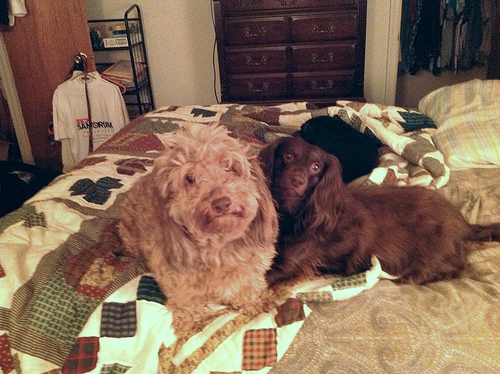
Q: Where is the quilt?
A: On the bed.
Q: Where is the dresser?
A: Against the back wall.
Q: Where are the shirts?
A: Hanging on the doorknob.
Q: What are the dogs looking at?
A: The camera.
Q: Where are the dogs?
A: On the bed.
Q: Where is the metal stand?
A: Behind the door.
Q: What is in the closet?
A: Clothing.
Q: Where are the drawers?
A: In the dresser.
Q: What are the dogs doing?
A: Lying on the bed.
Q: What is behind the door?
A: A metal stand.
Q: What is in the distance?
A: Dresser.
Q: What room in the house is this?
A: Bedroom.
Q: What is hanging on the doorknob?
A: Shirts.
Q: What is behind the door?
A: Rack.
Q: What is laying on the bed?
A: Dogs.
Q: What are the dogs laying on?
A: Bed.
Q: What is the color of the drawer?
A: Dark brown.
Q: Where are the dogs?
A: On the bed.